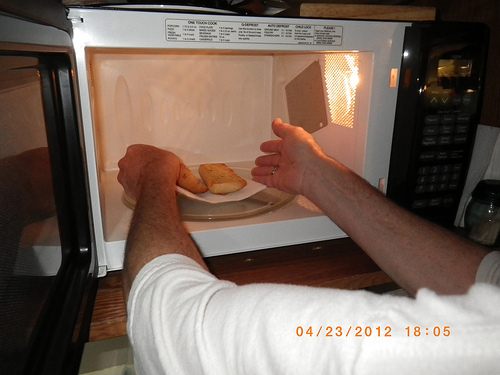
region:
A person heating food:
[109, 115, 497, 374]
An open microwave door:
[1, 0, 102, 374]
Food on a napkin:
[171, 158, 268, 208]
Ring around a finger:
[265, 160, 280, 181]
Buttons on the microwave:
[409, 90, 475, 212]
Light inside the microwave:
[317, 45, 363, 132]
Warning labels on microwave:
[161, 14, 345, 49]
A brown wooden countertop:
[86, 235, 392, 342]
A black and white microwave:
[1, 0, 494, 374]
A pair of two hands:
[114, 113, 324, 200]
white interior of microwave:
[45, 7, 411, 277]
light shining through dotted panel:
[305, 55, 362, 125]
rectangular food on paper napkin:
[175, 145, 260, 205]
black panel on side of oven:
[381, 16, 483, 221]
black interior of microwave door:
[0, 11, 95, 371]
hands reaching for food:
[102, 95, 367, 220]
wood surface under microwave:
[90, 236, 410, 331]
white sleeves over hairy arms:
[122, 171, 497, 366]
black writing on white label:
[162, 15, 342, 45]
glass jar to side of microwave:
[458, 125, 495, 255]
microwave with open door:
[2, 4, 493, 373]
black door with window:
[2, 8, 96, 373]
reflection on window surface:
[1, 64, 67, 359]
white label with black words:
[165, 18, 343, 45]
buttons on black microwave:
[403, 25, 488, 211]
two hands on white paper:
[115, 119, 364, 236]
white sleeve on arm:
[117, 141, 498, 373]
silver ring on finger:
[250, 116, 310, 193]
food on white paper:
[172, 158, 264, 203]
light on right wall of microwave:
[84, 51, 373, 243]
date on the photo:
[291, 320, 448, 344]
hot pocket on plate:
[178, 165, 231, 200]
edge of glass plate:
[221, 205, 247, 227]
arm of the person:
[243, 120, 435, 290]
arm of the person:
[135, 133, 171, 261]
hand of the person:
[251, 121, 320, 196]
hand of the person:
[93, 133, 168, 185]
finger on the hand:
[264, 110, 294, 130]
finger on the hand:
[257, 139, 275, 151]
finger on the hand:
[250, 153, 269, 165]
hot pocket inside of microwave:
[200, 163, 245, 193]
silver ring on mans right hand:
[270, 163, 282, 175]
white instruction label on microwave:
[164, 19, 344, 44]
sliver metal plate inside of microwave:
[289, 60, 328, 127]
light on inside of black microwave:
[329, 51, 361, 127]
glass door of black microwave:
[0, 44, 77, 284]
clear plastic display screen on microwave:
[434, 56, 475, 81]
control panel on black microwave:
[412, 54, 469, 220]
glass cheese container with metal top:
[465, 180, 497, 248]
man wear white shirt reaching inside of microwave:
[124, 254, 476, 373]